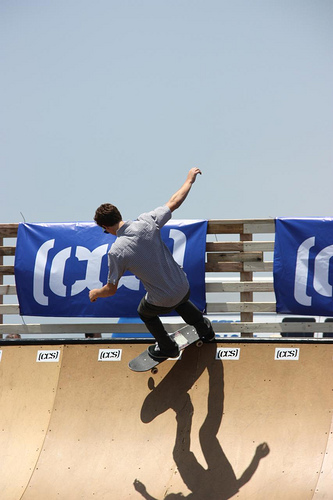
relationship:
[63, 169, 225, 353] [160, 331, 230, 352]
man doing tricks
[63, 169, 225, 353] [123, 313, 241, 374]
man riding skateboard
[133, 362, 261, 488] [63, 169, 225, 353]
shadow of man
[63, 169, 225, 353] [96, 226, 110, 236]
man wearing sunglasses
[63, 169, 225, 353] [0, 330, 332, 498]
man on halfpipe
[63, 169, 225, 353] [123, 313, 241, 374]
man on skateboard